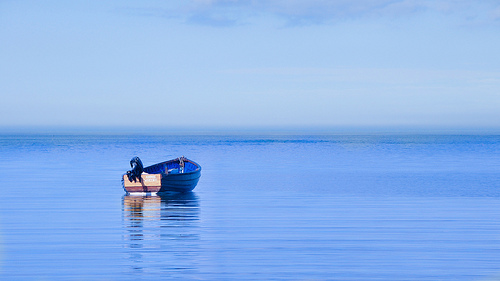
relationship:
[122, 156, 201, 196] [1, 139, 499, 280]
boat on water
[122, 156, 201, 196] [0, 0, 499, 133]
boat under sky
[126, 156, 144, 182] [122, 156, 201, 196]
engine on boat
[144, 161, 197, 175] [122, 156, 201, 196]
shadow on boat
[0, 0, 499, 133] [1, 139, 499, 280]
sky above water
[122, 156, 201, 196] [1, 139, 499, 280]
boat in water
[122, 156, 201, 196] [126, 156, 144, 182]
boat has engine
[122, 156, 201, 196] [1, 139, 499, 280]
boat floating on water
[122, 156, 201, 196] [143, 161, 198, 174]
boat has interior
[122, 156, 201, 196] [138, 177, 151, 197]
boat has shadow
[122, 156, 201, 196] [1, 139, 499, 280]
boat reflects on water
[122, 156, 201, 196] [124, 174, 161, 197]
boat has stern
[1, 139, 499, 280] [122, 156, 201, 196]
water holds boat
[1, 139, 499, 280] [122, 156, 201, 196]
water has boat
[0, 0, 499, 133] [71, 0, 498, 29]
sky has cloud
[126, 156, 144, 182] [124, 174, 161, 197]
engine on stern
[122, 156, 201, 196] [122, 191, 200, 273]
boat has reflection